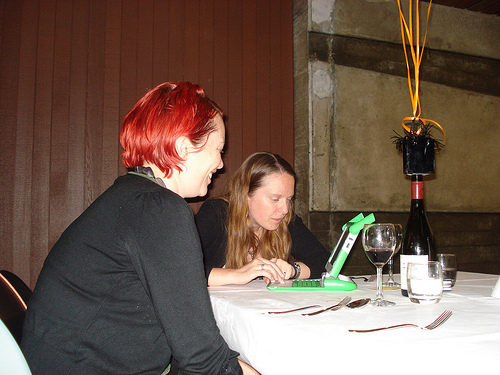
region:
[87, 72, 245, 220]
woman has red hair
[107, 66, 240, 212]
woman is smiling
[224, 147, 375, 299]
woman is touching the lap top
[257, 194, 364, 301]
the lap top is green and white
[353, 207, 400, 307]
the glass has wine in it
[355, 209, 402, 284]
the wine is red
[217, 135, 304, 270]
the woman has brown hair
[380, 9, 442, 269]
the bottle top is decorated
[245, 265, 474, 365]
the table cloth is white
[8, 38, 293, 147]
the wall is brown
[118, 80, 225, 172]
short red hair on woman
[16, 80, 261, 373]
woman sitting at a dining table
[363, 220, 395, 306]
glass on table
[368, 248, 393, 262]
red wine in glass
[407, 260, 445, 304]
glass tumbler on table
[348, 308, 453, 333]
silver metal fork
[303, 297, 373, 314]
spoon next to fork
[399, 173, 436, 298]
wine bottle next to wine glass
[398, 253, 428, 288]
white label on wine bottle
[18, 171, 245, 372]
woman wearing a black shirt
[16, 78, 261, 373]
A lady with red hair.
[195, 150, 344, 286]
A lady with brown hair.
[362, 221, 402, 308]
Two clear wine glasses.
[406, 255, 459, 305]
Two glasses of water.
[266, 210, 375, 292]
A green laptop on the table.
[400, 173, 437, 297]
A wine bottle on the table.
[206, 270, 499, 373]
A tablecloth on a table.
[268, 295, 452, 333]
Silverware on a table.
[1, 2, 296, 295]
A wood panel wall.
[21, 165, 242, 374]
A girls black top.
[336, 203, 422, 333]
A wine glass on a table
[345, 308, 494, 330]
A fork on a table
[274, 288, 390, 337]
A spoon on a table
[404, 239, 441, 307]
A short glass of water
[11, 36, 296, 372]
A woman with red hair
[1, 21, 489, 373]
Two women sitting at a table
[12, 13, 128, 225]
A wall near a table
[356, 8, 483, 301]
A vase on a table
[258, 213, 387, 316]
A green computer on a table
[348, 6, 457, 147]
Balloon strings on a table